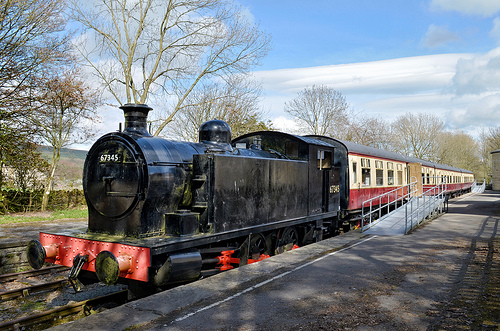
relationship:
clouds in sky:
[0, 1, 499, 150] [275, 5, 496, 80]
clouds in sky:
[0, 1, 499, 150] [1, 0, 499, 151]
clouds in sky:
[0, 1, 499, 150] [259, 2, 493, 89]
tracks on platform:
[421, 288, 486, 317] [42, 183, 498, 327]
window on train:
[361, 157, 373, 188] [42, 116, 474, 276]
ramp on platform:
[360, 175, 448, 236] [42, 183, 498, 327]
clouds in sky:
[0, 1, 499, 150] [286, 19, 351, 49]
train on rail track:
[66, 84, 497, 256] [0, 226, 147, 325]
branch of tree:
[67, 9, 248, 99] [60, 0, 272, 139]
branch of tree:
[162, 20, 225, 44] [60, 0, 272, 139]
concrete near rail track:
[118, 165, 494, 327] [0, 226, 147, 325]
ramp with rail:
[360, 175, 448, 236] [403, 173, 468, 236]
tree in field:
[34, 68, 91, 210] [1, 185, 82, 226]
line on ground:
[224, 285, 251, 301] [52, 285, 479, 320]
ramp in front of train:
[360, 175, 448, 236] [25, 102, 475, 294]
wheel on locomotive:
[249, 237, 267, 258] [26, 102, 341, 292]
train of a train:
[42, 116, 474, 276] [25, 102, 475, 294]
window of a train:
[358, 157, 373, 194] [25, 102, 475, 294]